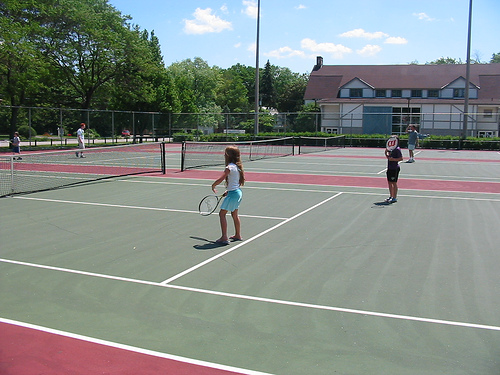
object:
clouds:
[177, 5, 238, 37]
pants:
[219, 187, 243, 212]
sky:
[114, 2, 500, 72]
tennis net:
[299, 134, 346, 154]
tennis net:
[179, 136, 295, 172]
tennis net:
[0, 141, 169, 198]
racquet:
[385, 135, 400, 158]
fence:
[0, 104, 499, 152]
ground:
[0, 197, 500, 317]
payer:
[75, 123, 86, 159]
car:
[121, 129, 131, 137]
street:
[0, 125, 186, 148]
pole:
[461, 0, 474, 139]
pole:
[253, 0, 261, 138]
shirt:
[223, 162, 241, 191]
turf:
[403, 222, 460, 262]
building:
[302, 55, 500, 140]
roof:
[301, 63, 500, 103]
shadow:
[189, 239, 243, 251]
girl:
[209, 145, 246, 245]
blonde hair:
[223, 144, 246, 186]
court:
[0, 136, 500, 375]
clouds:
[338, 23, 390, 42]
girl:
[384, 135, 405, 204]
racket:
[197, 190, 229, 217]